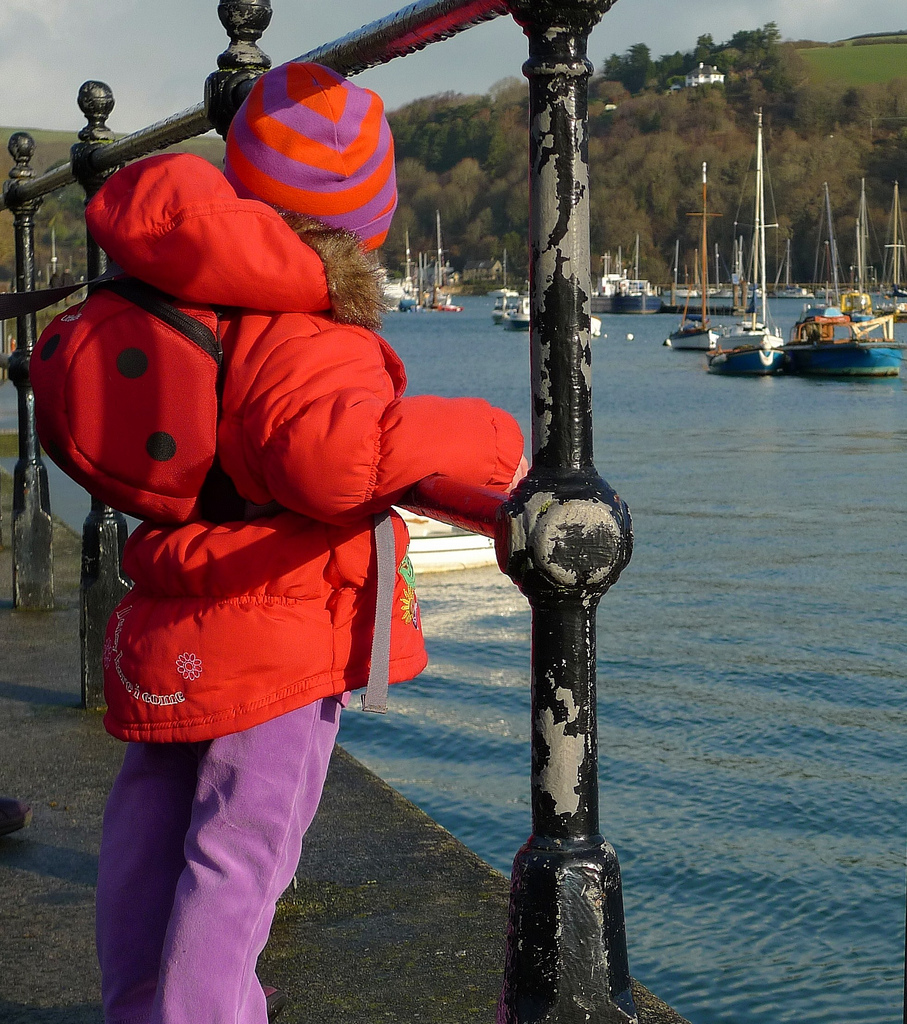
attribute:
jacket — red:
[58, 165, 539, 738]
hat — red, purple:
[223, 56, 414, 247]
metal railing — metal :
[513, 6, 651, 1008]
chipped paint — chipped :
[530, 669, 627, 845]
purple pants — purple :
[104, 677, 346, 1018]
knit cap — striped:
[220, 62, 403, 249]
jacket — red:
[77, 150, 515, 743]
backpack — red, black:
[31, 268, 230, 521]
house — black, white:
[687, 59, 729, 90]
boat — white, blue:
[710, 316, 787, 378]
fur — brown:
[288, 216, 386, 329]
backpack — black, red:
[24, 268, 226, 535]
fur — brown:
[300, 220, 395, 325]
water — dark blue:
[633, 390, 845, 1018]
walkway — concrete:
[3, 463, 95, 1010]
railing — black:
[504, 6, 635, 1020]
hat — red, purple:
[232, 64, 398, 258]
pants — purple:
[98, 702, 345, 1016]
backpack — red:
[31, 305, 223, 521]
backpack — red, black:
[41, 268, 238, 541]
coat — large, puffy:
[239, 364, 428, 510]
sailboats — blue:
[779, 318, 879, 375]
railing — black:
[514, 714, 675, 1024]